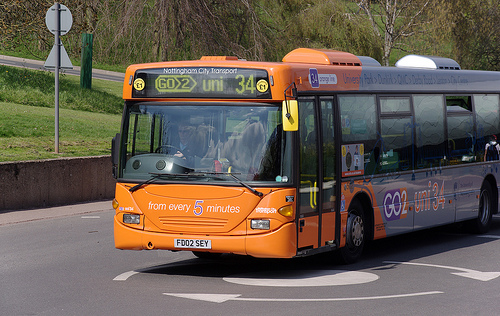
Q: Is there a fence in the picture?
A: No, there are no fences.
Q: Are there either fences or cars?
A: No, there are no fences or cars.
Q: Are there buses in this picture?
A: Yes, there is a bus.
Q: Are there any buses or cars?
A: Yes, there is a bus.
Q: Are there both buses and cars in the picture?
A: No, there is a bus but no cars.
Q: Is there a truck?
A: No, there are no trucks.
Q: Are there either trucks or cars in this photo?
A: No, there are no trucks or cars.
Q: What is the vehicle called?
A: The vehicle is a bus.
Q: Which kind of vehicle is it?
A: The vehicle is a bus.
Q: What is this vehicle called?
A: This is a bus.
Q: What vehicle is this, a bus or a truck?
A: This is a bus.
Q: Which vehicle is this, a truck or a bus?
A: This is a bus.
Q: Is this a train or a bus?
A: This is a bus.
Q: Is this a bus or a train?
A: This is a bus.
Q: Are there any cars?
A: No, there are no cars.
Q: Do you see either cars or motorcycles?
A: No, there are no cars or motorcycles.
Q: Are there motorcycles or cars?
A: No, there are no cars or motorcycles.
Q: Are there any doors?
A: Yes, there is a door.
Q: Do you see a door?
A: Yes, there is a door.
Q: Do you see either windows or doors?
A: Yes, there is a door.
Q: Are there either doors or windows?
A: Yes, there is a door.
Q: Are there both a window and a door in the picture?
A: Yes, there are both a door and a window.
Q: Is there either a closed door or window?
A: Yes, there is a closed door.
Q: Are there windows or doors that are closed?
A: Yes, the door is closed.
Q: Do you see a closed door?
A: Yes, there is a closed door.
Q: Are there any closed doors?
A: Yes, there is a closed door.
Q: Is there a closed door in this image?
A: Yes, there is a closed door.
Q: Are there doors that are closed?
A: Yes, there is a door that is closed.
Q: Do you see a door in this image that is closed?
A: Yes, there is a door that is closed.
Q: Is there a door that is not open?
A: Yes, there is an closed door.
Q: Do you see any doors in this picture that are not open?
A: Yes, there is an closed door.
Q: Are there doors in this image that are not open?
A: Yes, there is an closed door.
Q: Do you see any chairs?
A: No, there are no chairs.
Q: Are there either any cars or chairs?
A: No, there are no chairs or cars.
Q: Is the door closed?
A: Yes, the door is closed.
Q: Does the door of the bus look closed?
A: Yes, the door is closed.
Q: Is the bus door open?
A: No, the door is closed.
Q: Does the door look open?
A: No, the door is closed.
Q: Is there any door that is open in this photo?
A: No, there is a door but it is closed.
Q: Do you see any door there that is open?
A: No, there is a door but it is closed.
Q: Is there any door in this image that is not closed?
A: No, there is a door but it is closed.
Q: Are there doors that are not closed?
A: No, there is a door but it is closed.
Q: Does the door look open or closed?
A: The door is closed.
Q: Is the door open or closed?
A: The door is closed.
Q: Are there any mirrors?
A: Yes, there is a mirror.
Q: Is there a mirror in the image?
A: Yes, there is a mirror.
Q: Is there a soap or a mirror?
A: Yes, there is a mirror.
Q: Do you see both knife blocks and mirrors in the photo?
A: No, there is a mirror but no knife blocks.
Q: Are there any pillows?
A: No, there are no pillows.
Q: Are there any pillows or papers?
A: No, there are no pillows or papers.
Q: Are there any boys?
A: No, there are no boys.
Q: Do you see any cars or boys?
A: No, there are no boys or cars.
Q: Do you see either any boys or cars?
A: No, there are no boys or cars.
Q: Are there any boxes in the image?
A: No, there are no boxes.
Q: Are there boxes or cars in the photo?
A: No, there are no boxes or cars.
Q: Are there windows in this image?
A: Yes, there are windows.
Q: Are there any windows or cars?
A: Yes, there are windows.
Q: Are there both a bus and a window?
A: Yes, there are both a window and a bus.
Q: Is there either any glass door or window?
A: Yes, there are glass windows.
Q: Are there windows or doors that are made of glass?
A: Yes, the windows are made of glass.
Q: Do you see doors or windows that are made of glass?
A: Yes, the windows are made of glass.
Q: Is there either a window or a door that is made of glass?
A: Yes, the windows are made of glass.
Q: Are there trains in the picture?
A: No, there are no trains.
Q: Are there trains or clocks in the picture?
A: No, there are no trains or clocks.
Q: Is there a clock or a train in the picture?
A: No, there are no trains or clocks.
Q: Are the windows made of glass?
A: Yes, the windows are made of glass.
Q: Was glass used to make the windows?
A: Yes, the windows are made of glass.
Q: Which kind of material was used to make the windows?
A: The windows are made of glass.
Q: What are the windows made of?
A: The windows are made of glass.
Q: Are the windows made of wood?
A: No, the windows are made of glass.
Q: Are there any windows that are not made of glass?
A: No, there are windows but they are made of glass.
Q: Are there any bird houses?
A: No, there are no bird houses.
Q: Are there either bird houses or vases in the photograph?
A: No, there are no bird houses or vases.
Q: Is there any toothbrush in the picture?
A: No, there are no toothbrushes.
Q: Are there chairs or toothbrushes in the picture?
A: No, there are no toothbrushes or chairs.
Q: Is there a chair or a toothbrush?
A: No, there are no toothbrushes or chairs.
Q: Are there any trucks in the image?
A: No, there are no trucks.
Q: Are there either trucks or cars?
A: No, there are no trucks or cars.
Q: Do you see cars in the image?
A: No, there are no cars.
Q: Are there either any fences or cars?
A: No, there are no cars or fences.